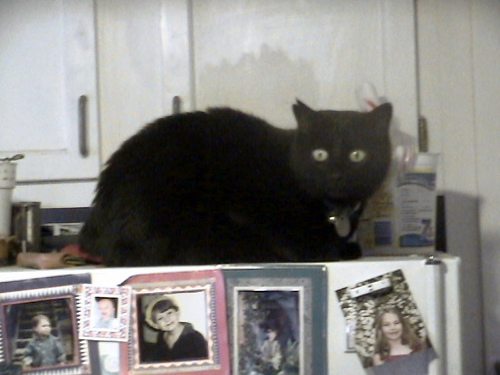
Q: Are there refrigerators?
A: Yes, there is a refrigerator.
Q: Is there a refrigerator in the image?
A: Yes, there is a refrigerator.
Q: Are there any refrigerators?
A: Yes, there is a refrigerator.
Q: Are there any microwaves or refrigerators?
A: Yes, there is a refrigerator.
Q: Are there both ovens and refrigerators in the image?
A: No, there is a refrigerator but no ovens.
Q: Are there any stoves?
A: No, there are no stoves.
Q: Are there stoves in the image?
A: No, there are no stoves.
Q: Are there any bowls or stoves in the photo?
A: No, there are no stoves or bowls.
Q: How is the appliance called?
A: The appliance is a refrigerator.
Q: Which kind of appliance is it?
A: The appliance is a refrigerator.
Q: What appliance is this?
A: This is a refrigerator.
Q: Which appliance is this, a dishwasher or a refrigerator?
A: This is a refrigerator.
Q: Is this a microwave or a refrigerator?
A: This is a refrigerator.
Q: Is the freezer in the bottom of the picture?
A: Yes, the freezer is in the bottom of the image.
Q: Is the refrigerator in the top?
A: No, the refrigerator is in the bottom of the image.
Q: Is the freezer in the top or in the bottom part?
A: The freezer is in the bottom of the image.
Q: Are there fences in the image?
A: No, there are no fences.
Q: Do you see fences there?
A: No, there are no fences.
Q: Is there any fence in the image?
A: No, there are no fences.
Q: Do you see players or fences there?
A: No, there are no fences or players.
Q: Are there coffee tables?
A: No, there are no coffee tables.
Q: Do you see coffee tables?
A: No, there are no coffee tables.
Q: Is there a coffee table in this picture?
A: No, there are no coffee tables.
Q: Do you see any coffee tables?
A: No, there are no coffee tables.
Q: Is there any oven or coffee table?
A: No, there are no coffee tables or ovens.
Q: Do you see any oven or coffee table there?
A: No, there are no coffee tables or ovens.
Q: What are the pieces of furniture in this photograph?
A: The pieces of furniture are cabinets.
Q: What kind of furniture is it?
A: The pieces of furniture are cabinets.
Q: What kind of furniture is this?
A: These are cabinets.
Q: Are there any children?
A: Yes, there is a child.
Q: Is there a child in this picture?
A: Yes, there is a child.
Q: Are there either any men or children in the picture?
A: Yes, there is a child.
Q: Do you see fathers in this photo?
A: No, there are no fathers.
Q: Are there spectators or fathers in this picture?
A: No, there are no fathers or spectators.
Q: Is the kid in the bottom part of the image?
A: Yes, the kid is in the bottom of the image.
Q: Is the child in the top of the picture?
A: No, the child is in the bottom of the image.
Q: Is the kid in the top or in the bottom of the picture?
A: The kid is in the bottom of the image.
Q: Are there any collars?
A: Yes, there is a collar.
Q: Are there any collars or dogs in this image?
A: Yes, there is a collar.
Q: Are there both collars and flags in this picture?
A: No, there is a collar but no flags.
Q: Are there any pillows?
A: No, there are no pillows.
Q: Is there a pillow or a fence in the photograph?
A: No, there are no pillows or fences.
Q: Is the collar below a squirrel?
A: No, the collar is below the cat.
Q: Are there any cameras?
A: Yes, there is a camera.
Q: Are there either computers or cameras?
A: Yes, there is a camera.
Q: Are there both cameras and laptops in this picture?
A: No, there is a camera but no laptops.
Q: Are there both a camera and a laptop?
A: No, there is a camera but no laptops.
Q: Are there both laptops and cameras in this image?
A: No, there is a camera but no laptops.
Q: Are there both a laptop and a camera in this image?
A: No, there is a camera but no laptops.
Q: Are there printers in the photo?
A: No, there are no printers.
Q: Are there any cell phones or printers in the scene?
A: No, there are no printers or cell phones.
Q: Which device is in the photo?
A: The device is a camera.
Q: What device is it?
A: The device is a camera.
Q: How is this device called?
A: That is a camera.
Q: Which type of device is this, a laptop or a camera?
A: That is a camera.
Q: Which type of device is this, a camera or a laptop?
A: That is a camera.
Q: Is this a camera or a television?
A: This is a camera.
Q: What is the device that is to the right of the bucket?
A: The device is a camera.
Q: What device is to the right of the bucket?
A: The device is a camera.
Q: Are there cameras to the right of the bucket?
A: Yes, there is a camera to the right of the bucket.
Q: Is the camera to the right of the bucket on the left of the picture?
A: Yes, the camera is to the right of the bucket.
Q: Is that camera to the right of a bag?
A: No, the camera is to the right of the bucket.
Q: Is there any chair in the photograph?
A: No, there are no chairs.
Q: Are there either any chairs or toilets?
A: No, there are no chairs or toilets.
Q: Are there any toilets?
A: No, there are no toilets.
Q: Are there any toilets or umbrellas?
A: No, there are no toilets or umbrellas.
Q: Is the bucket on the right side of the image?
A: No, the bucket is on the left of the image.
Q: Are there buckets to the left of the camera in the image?
A: Yes, there is a bucket to the left of the camera.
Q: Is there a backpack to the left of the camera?
A: No, there is a bucket to the left of the camera.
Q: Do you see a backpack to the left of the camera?
A: No, there is a bucket to the left of the camera.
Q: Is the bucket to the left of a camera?
A: Yes, the bucket is to the left of a camera.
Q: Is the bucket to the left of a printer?
A: No, the bucket is to the left of a camera.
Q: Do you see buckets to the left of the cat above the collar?
A: Yes, there is a bucket to the left of the cat.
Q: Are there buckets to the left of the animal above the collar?
A: Yes, there is a bucket to the left of the cat.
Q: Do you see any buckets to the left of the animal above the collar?
A: Yes, there is a bucket to the left of the cat.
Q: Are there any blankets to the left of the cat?
A: No, there is a bucket to the left of the cat.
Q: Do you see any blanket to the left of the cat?
A: No, there is a bucket to the left of the cat.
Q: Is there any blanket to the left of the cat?
A: No, there is a bucket to the left of the cat.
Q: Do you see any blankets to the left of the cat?
A: No, there is a bucket to the left of the cat.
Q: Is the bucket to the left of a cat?
A: Yes, the bucket is to the left of a cat.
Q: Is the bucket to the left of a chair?
A: No, the bucket is to the left of a cat.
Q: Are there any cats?
A: Yes, there is a cat.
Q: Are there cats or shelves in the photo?
A: Yes, there is a cat.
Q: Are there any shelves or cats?
A: Yes, there is a cat.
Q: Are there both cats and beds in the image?
A: No, there is a cat but no beds.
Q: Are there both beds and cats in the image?
A: No, there is a cat but no beds.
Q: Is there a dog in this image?
A: No, there are no dogs.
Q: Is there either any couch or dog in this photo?
A: No, there are no dogs or couches.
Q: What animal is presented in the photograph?
A: The animal is a cat.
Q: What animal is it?
A: The animal is a cat.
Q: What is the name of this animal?
A: That is a cat.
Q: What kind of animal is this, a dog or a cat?
A: That is a cat.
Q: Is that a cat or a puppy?
A: That is a cat.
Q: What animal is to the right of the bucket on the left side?
A: The animal is a cat.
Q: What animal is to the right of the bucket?
A: The animal is a cat.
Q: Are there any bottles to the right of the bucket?
A: No, there is a cat to the right of the bucket.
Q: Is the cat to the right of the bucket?
A: Yes, the cat is to the right of the bucket.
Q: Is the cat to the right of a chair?
A: No, the cat is to the right of the bucket.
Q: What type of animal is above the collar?
A: The animal is a cat.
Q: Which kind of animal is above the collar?
A: The animal is a cat.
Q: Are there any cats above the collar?
A: Yes, there is a cat above the collar.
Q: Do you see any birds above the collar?
A: No, there is a cat above the collar.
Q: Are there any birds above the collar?
A: No, there is a cat above the collar.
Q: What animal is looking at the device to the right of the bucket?
A: The cat is looking at the camera.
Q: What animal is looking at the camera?
A: The cat is looking at the camera.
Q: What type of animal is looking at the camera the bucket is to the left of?
A: The animal is a cat.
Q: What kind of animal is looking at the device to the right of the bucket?
A: The animal is a cat.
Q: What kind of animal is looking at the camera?
A: The animal is a cat.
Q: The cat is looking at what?
A: The cat is looking at the camera.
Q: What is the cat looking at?
A: The cat is looking at the camera.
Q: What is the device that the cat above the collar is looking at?
A: The device is a camera.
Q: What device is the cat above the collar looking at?
A: The cat is looking at the camera.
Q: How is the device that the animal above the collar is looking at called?
A: The device is a camera.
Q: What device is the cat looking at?
A: The cat is looking at the camera.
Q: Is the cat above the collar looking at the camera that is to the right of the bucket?
A: Yes, the cat is looking at the camera.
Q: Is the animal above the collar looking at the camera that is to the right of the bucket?
A: Yes, the cat is looking at the camera.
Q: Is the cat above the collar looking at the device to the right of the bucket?
A: Yes, the cat is looking at the camera.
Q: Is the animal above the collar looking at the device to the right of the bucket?
A: Yes, the cat is looking at the camera.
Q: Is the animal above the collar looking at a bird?
A: No, the cat is looking at the camera.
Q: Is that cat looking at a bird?
A: No, the cat is looking at the camera.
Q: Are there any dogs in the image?
A: No, there are no dogs.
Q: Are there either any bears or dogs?
A: No, there are no dogs or bears.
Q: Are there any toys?
A: No, there are no toys.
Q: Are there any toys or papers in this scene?
A: No, there are no toys or papers.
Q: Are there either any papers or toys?
A: No, there are no toys or papers.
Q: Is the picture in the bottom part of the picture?
A: Yes, the picture is in the bottom of the image.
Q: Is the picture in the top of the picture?
A: No, the picture is in the bottom of the image.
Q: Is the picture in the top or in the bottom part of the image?
A: The picture is in the bottom of the image.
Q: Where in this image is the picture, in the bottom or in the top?
A: The picture is in the bottom of the image.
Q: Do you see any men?
A: No, there are no men.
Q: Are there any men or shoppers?
A: No, there are no men or shoppers.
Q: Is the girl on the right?
A: Yes, the girl is on the right of the image.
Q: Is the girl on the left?
A: No, the girl is on the right of the image.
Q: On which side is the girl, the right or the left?
A: The girl is on the right of the image.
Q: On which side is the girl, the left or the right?
A: The girl is on the right of the image.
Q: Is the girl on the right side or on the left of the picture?
A: The girl is on the right of the image.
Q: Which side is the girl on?
A: The girl is on the right of the image.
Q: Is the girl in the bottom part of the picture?
A: Yes, the girl is in the bottom of the image.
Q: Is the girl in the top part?
A: No, the girl is in the bottom of the image.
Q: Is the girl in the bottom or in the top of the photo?
A: The girl is in the bottom of the image.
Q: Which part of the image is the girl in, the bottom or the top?
A: The girl is in the bottom of the image.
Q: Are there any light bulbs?
A: No, there are no light bulbs.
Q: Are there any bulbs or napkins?
A: No, there are no bulbs or napkins.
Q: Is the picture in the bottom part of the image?
A: Yes, the picture is in the bottom of the image.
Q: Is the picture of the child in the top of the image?
A: No, the picture is in the bottom of the image.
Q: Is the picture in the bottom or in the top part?
A: The picture is in the bottom of the image.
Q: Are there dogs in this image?
A: No, there are no dogs.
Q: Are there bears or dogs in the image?
A: No, there are no dogs or bears.